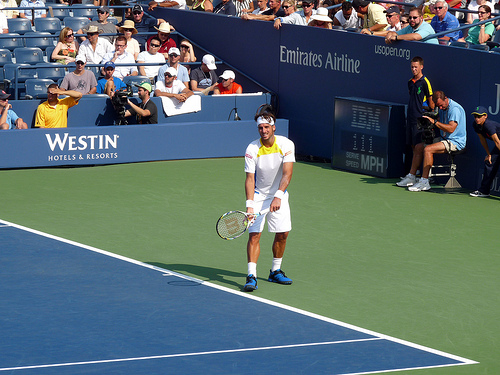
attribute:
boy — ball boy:
[470, 106, 499, 206]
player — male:
[241, 111, 295, 290]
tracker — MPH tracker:
[320, 75, 409, 180]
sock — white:
[246, 259, 256, 276]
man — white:
[239, 105, 296, 279]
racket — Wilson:
[205, 194, 295, 246]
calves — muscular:
[246, 229, 262, 265]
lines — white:
[65, 247, 467, 365]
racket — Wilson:
[216, 207, 269, 241]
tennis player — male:
[213, 105, 304, 290]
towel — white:
[159, 89, 203, 116]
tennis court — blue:
[2, 155, 497, 371]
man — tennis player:
[241, 100, 295, 292]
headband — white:
[253, 115, 274, 125]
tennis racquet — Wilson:
[210, 209, 265, 237]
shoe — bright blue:
[241, 273, 260, 292]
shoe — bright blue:
[269, 266, 293, 284]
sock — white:
[269, 257, 283, 270]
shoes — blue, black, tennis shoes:
[232, 250, 317, 311]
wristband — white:
[268, 187, 295, 204]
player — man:
[215, 109, 315, 299]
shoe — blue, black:
[229, 263, 304, 298]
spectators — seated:
[55, 12, 245, 116]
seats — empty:
[8, 17, 123, 92]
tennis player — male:
[238, 102, 300, 290]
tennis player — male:
[240, 105, 294, 292]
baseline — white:
[0, 215, 482, 373]